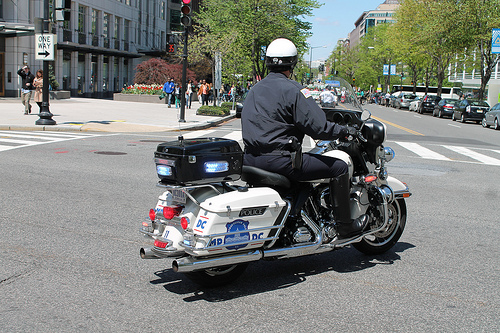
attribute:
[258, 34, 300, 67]
helmet — white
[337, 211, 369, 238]
boot — black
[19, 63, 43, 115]
couple — walking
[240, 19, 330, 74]
helmet — white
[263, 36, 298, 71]
helmet — black, white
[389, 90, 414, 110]
cars — parked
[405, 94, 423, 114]
cars — parked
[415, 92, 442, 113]
cars — parked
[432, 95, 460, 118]
cars — parked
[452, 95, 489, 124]
cars — parked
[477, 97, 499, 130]
cars — parked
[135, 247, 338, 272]
exhaust pipes — long, chrome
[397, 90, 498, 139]
car — parked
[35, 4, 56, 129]
pole — black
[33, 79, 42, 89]
arms — crossed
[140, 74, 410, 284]
bikw — police